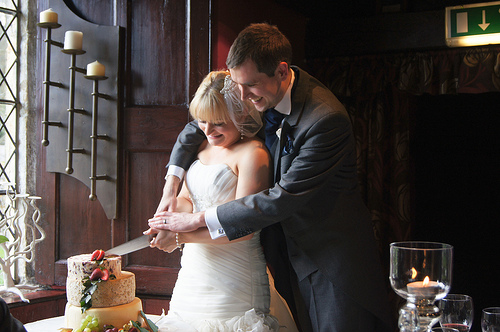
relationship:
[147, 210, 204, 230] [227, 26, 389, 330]
hand of a man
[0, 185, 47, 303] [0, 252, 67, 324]
tree on window sill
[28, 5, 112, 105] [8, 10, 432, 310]
candles on wall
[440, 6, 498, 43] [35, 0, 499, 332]
sign on wall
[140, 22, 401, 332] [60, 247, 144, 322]
couple cuts wedding cake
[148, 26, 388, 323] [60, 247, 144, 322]
groom cuts wedding cake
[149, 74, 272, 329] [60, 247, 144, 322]
bride cuts wedding cake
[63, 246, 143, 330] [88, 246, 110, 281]
wedding cake has flowers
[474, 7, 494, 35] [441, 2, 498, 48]
arrow on sign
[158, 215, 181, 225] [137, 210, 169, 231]
ring on finger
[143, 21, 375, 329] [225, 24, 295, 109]
man has head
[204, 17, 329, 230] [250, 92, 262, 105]
man has lips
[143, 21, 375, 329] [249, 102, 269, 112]
man has chin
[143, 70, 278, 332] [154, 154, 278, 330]
woman wearing dress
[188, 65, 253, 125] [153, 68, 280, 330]
hair belonging to woman's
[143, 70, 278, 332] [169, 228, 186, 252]
woman wearing bracelet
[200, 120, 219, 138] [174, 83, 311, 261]
nose of woman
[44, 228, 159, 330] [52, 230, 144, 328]
knife cutting cake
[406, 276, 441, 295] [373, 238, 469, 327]
candle in glass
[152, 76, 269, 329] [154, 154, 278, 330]
woman in dress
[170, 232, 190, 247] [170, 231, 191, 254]
wrist has pearls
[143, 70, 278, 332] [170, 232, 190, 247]
woman has wrist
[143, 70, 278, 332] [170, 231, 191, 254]
woman has pearls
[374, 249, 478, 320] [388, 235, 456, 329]
candle in glass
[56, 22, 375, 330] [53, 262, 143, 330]
couple cutting cake